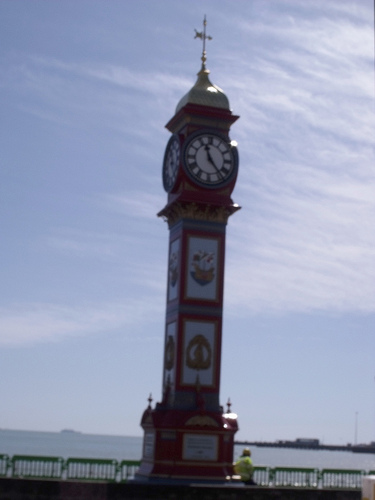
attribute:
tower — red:
[131, 13, 239, 484]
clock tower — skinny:
[132, 15, 242, 483]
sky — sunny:
[2, 1, 132, 423]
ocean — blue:
[3, 427, 374, 484]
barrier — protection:
[253, 467, 364, 488]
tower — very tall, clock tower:
[142, 68, 242, 473]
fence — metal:
[30, 440, 160, 487]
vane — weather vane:
[192, 17, 218, 59]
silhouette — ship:
[54, 423, 85, 437]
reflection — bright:
[184, 474, 259, 491]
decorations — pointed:
[182, 239, 223, 384]